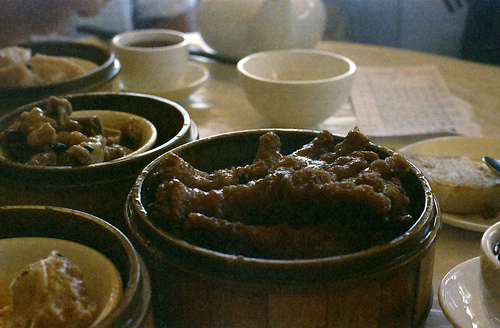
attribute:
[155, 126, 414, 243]
food — beef, brown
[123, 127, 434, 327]
bowl — wooden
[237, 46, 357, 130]
bowl — white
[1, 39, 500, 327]
table — white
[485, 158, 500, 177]
spoon — metal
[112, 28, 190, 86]
cup — white